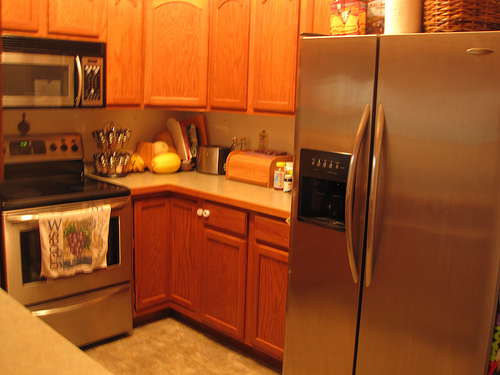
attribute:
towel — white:
[40, 203, 112, 279]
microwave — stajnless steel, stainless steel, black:
[0, 43, 107, 110]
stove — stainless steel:
[3, 133, 135, 347]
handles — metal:
[343, 105, 385, 286]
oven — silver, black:
[5, 196, 132, 307]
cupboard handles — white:
[195, 209, 211, 219]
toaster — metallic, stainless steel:
[197, 143, 230, 174]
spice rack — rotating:
[93, 120, 133, 180]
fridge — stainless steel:
[279, 31, 497, 374]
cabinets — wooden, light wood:
[1, 2, 359, 113]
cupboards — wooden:
[136, 195, 289, 360]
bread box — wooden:
[224, 151, 288, 186]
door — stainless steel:
[282, 32, 492, 374]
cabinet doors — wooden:
[146, 2, 363, 110]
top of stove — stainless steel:
[2, 170, 129, 208]